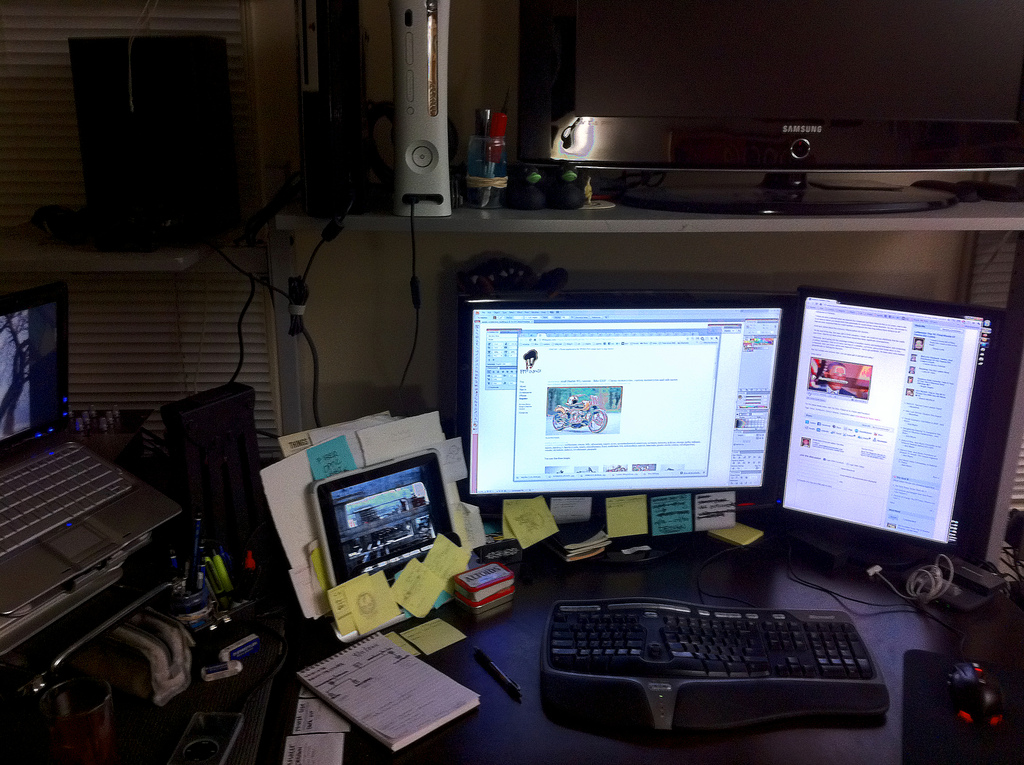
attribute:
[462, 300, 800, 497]
monitor screen — on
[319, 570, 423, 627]
sticky — yellow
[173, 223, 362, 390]
cords — black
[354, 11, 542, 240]
speaker — black